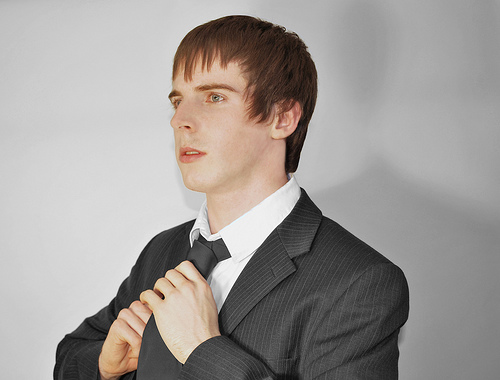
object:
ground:
[325, 148, 351, 185]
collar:
[182, 200, 294, 267]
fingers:
[116, 250, 198, 357]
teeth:
[184, 151, 195, 153]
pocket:
[263, 358, 302, 377]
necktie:
[139, 243, 245, 374]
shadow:
[278, 2, 498, 377]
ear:
[260, 94, 308, 156]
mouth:
[168, 148, 205, 161]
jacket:
[31, 198, 406, 378]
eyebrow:
[198, 85, 247, 97]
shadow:
[326, 46, 448, 253]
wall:
[17, 14, 498, 371]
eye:
[204, 90, 229, 106]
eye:
[170, 96, 185, 108]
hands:
[99, 259, 222, 379]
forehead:
[171, 63, 253, 90]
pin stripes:
[282, 236, 406, 373]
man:
[49, 17, 409, 377]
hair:
[176, 23, 313, 133]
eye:
[205, 97, 223, 104]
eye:
[174, 101, 184, 111]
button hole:
[262, 265, 285, 277]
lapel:
[216, 188, 322, 338]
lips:
[177, 144, 207, 165]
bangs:
[165, 29, 246, 70]